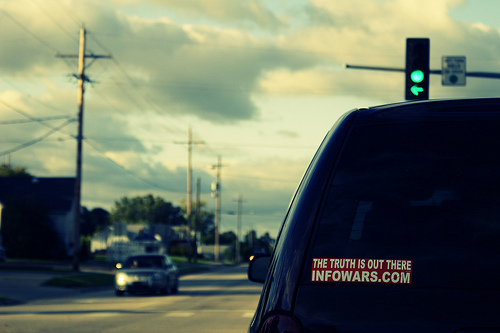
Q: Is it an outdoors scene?
A: Yes, it is outdoors.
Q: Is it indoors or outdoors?
A: It is outdoors.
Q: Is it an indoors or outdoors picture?
A: It is outdoors.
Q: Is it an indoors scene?
A: No, it is outdoors.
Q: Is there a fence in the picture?
A: No, there are no fences.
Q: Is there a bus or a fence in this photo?
A: No, there are no fences or buses.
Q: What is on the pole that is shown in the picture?
A: The sign is on the pole.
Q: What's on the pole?
A: The sign is on the pole.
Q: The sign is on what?
A: The sign is on the pole.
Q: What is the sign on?
A: The sign is on the pole.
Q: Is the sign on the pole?
A: Yes, the sign is on the pole.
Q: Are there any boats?
A: No, there are no boats.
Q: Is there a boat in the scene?
A: No, there are no boats.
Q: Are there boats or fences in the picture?
A: No, there are no boats or fences.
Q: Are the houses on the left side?
A: Yes, the houses are on the left of the image.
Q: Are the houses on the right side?
A: No, the houses are on the left of the image.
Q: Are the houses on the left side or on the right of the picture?
A: The houses are on the left of the image.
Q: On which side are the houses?
A: The houses are on the left of the image.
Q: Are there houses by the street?
A: Yes, there are houses by the street.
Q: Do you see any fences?
A: No, there are no fences.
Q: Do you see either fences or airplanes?
A: No, there are no fences or airplanes.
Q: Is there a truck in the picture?
A: No, there are no trucks.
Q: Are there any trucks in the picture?
A: No, there are no trucks.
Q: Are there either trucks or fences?
A: No, there are no trucks or fences.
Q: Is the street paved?
A: Yes, the street is paved.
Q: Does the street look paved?
A: Yes, the street is paved.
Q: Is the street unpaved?
A: No, the street is paved.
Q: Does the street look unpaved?
A: No, the street is paved.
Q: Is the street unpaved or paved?
A: The street is paved.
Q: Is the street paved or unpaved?
A: The street is paved.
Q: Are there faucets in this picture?
A: No, there are no faucets.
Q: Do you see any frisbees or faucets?
A: No, there are no faucets or frisbees.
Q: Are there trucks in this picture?
A: No, there are no trucks.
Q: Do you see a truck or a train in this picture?
A: No, there are no trucks or trains.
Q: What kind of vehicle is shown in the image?
A: The vehicle is a car.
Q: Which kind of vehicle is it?
A: The vehicle is a car.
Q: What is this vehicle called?
A: This is a car.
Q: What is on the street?
A: The car is on the street.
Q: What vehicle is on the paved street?
A: The vehicle is a car.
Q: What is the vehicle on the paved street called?
A: The vehicle is a car.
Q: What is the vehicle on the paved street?
A: The vehicle is a car.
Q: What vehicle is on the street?
A: The vehicle is a car.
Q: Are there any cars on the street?
A: Yes, there is a car on the street.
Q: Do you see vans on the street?
A: No, there is a car on the street.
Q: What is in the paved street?
A: The car is in the street.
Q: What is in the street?
A: The car is in the street.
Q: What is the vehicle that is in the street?
A: The vehicle is a car.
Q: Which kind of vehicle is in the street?
A: The vehicle is a car.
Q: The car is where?
A: The car is in the street.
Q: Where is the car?
A: The car is in the street.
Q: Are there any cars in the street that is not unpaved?
A: Yes, there is a car in the street.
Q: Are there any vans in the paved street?
A: No, there is a car in the street.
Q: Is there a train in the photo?
A: No, there are no trains.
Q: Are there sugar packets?
A: No, there are no sugar packets.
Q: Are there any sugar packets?
A: No, there are no sugar packets.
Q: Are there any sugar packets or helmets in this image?
A: No, there are no sugar packets or helmets.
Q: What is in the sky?
A: The powerlines are in the sky.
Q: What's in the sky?
A: The powerlines are in the sky.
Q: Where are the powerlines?
A: The powerlines are in the sky.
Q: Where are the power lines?
A: The powerlines are in the sky.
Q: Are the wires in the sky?
A: Yes, the wires are in the sky.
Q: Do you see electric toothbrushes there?
A: No, there are no electric toothbrushes.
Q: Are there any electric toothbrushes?
A: No, there are no electric toothbrushes.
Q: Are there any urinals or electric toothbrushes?
A: No, there are no electric toothbrushes or urinals.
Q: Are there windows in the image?
A: Yes, there is a window.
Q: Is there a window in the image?
A: Yes, there is a window.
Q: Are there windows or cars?
A: Yes, there is a window.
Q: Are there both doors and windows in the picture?
A: No, there is a window but no doors.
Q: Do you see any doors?
A: No, there are no doors.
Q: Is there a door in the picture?
A: No, there are no doors.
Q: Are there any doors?
A: No, there are no doors.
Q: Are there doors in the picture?
A: No, there are no doors.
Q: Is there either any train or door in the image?
A: No, there are no doors or trains.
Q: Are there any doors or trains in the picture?
A: No, there are no doors or trains.